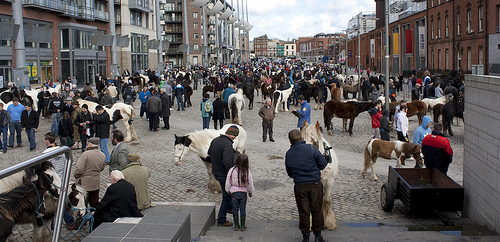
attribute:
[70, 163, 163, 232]
man — sitting, wearing, walking, standing, take car, walks, check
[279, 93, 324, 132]
person — wearing, standing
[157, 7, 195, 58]
building — brick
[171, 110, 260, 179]
horse — brown, white, wait, black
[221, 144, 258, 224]
girl — standing, looking, look, little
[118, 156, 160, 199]
jacket — brown, black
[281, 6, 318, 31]
cloud — white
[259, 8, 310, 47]
sky — blue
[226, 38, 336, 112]
people — standing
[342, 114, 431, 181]
pony — brown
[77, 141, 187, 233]
men — sit, walk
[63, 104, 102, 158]
lady — walk away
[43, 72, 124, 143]
group — talk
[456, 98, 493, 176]
wall — grey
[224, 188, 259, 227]
jean — blue